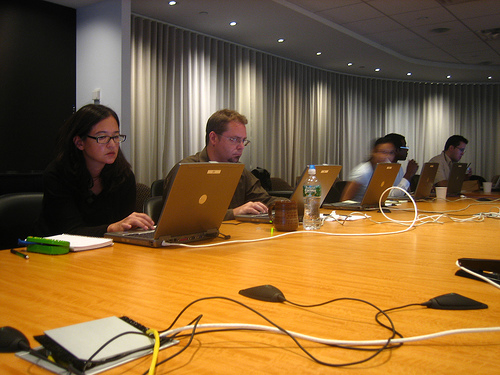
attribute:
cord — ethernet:
[153, 284, 402, 374]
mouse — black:
[420, 289, 492, 318]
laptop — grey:
[116, 166, 242, 240]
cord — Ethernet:
[134, 315, 174, 372]